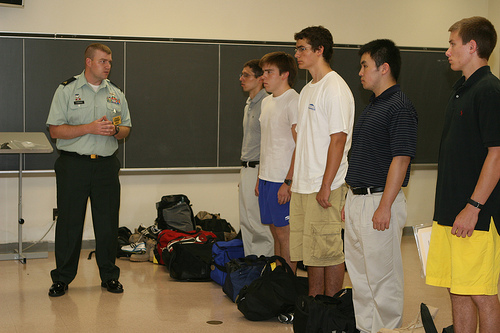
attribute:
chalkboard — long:
[0, 33, 462, 168]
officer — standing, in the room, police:
[45, 43, 133, 296]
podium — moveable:
[1, 131, 51, 263]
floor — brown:
[1, 233, 497, 333]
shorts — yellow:
[424, 215, 499, 297]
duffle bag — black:
[169, 246, 211, 276]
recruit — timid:
[431, 17, 500, 333]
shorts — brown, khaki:
[289, 187, 346, 267]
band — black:
[466, 196, 483, 211]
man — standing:
[290, 30, 356, 300]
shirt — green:
[242, 93, 266, 159]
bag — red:
[231, 255, 308, 319]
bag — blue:
[210, 235, 246, 283]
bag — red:
[155, 229, 213, 263]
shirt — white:
[294, 74, 355, 194]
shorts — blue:
[256, 177, 293, 227]